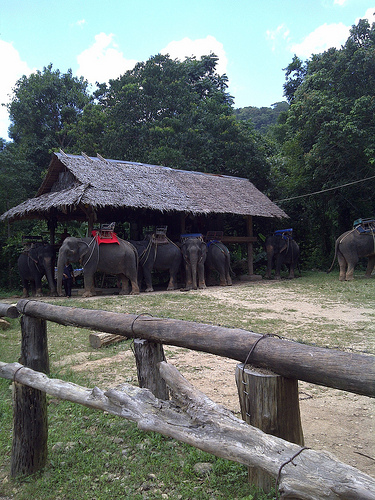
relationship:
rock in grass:
[192, 461, 211, 478] [3, 367, 373, 499]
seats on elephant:
[176, 230, 203, 241] [176, 230, 210, 294]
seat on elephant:
[98, 221, 115, 239] [58, 229, 140, 297]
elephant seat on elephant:
[142, 224, 169, 244] [128, 233, 182, 292]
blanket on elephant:
[91, 230, 119, 245] [52, 231, 145, 300]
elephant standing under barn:
[57, 233, 140, 298] [0, 149, 294, 296]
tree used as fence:
[93, 40, 373, 181] [0, 296, 374, 495]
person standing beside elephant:
[63, 260, 74, 297] [56, 235, 140, 296]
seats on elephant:
[352, 215, 373, 234] [327, 223, 375, 281]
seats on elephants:
[273, 224, 293, 239] [263, 232, 303, 280]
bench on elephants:
[205, 231, 223, 241] [203, 237, 236, 286]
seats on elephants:
[179, 233, 203, 242] [178, 232, 209, 291]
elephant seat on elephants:
[142, 224, 169, 244] [125, 234, 184, 293]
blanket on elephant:
[91, 230, 119, 245] [57, 233, 140, 298]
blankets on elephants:
[205, 238, 223, 250] [203, 237, 236, 286]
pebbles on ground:
[49, 422, 202, 497] [0, 284, 372, 494]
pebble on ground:
[143, 468, 156, 480] [0, 263, 373, 498]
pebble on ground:
[157, 475, 164, 485] [0, 263, 373, 498]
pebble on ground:
[161, 490, 170, 498] [0, 263, 373, 498]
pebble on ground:
[139, 477, 149, 486] [0, 263, 373, 498]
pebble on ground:
[134, 481, 145, 492] [0, 263, 373, 498]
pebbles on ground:
[231, 286, 280, 309] [200, 262, 302, 319]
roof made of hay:
[55, 152, 290, 220] [169, 176, 196, 195]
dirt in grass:
[202, 284, 373, 323] [84, 276, 373, 345]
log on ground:
[5, 357, 374, 498] [0, 284, 372, 494]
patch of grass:
[176, 299, 223, 317] [8, 271, 368, 489]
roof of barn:
[0, 150, 291, 219] [0, 144, 294, 296]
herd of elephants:
[37, 227, 236, 289] [44, 229, 239, 299]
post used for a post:
[10, 302, 49, 473] [7, 302, 55, 472]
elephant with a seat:
[64, 233, 140, 288] [94, 229, 120, 243]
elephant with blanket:
[322, 228, 372, 282] [275, 233, 293, 240]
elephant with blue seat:
[203, 237, 236, 286] [179, 229, 201, 241]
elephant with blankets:
[267, 234, 303, 277] [206, 240, 220, 248]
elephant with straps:
[136, 220, 199, 303] [150, 245, 160, 268]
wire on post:
[229, 328, 288, 404] [229, 357, 308, 445]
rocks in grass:
[94, 447, 178, 486] [0, 405, 274, 498]